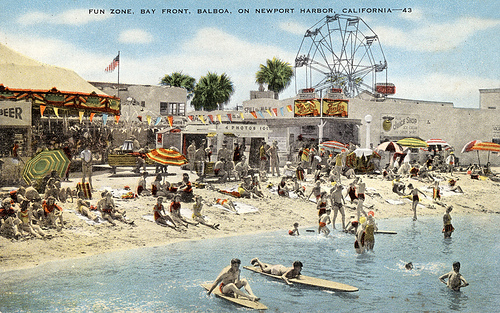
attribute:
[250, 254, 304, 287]
man — young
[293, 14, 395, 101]
ride — tall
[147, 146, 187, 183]
umbrella — striped, open, red, yellow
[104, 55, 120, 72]
flag — american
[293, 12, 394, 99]
ferris wheel — ferris 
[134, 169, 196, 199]
people — enjoying the sun, enjoying time off, having great time, enjoying their day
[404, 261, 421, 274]
person — swimming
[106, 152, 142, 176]
bench — wooden